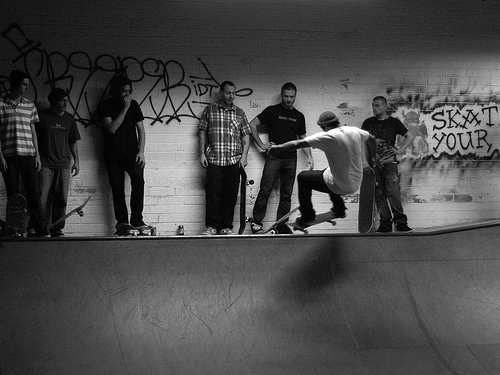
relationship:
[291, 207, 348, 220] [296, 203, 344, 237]
feet on skateboard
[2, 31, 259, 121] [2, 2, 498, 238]
graffiti on wall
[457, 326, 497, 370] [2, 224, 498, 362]
patch on ramp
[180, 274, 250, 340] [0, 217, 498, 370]
scuff mark on ramp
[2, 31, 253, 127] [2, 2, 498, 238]
graffiti on wall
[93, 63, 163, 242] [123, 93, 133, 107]
man covering mouth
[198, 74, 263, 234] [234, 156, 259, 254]
man holding skateboard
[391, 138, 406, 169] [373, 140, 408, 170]
hand on hip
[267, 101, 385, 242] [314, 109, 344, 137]
man wearing hat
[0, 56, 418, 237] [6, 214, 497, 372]
men standing on side of skateboard ramp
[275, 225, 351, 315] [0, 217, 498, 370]
shadow on ramp